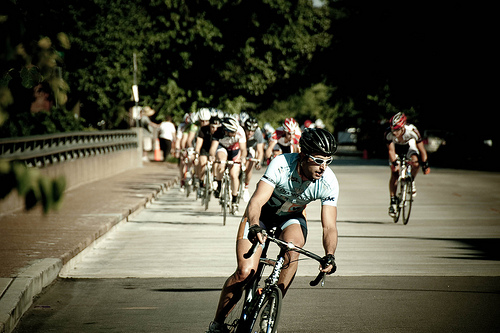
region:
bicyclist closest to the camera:
[207, 126, 341, 330]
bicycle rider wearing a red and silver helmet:
[381, 113, 429, 228]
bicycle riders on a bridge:
[172, 102, 431, 332]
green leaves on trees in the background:
[0, 2, 299, 84]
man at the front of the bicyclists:
[216, 127, 340, 328]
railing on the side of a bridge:
[0, 127, 143, 161]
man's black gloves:
[246, 222, 335, 274]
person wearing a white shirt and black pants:
[157, 115, 175, 161]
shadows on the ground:
[417, 228, 499, 268]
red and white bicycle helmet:
[281, 118, 298, 133]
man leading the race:
[216, 128, 368, 332]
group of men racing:
[172, 96, 429, 332]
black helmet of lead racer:
[296, 124, 335, 155]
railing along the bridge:
[2, 106, 144, 205]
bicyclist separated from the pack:
[385, 111, 420, 226]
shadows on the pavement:
[151, 194, 498, 298]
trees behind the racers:
[8, 4, 499, 141]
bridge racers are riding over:
[94, 139, 495, 332]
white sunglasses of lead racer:
[305, 151, 333, 166]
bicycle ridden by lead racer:
[200, 227, 337, 332]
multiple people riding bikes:
[103, 48, 474, 330]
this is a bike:
[225, 205, 343, 330]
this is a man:
[198, 121, 374, 329]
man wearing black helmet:
[288, 102, 351, 187]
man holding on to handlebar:
[245, 218, 344, 298]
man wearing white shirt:
[256, 147, 344, 234]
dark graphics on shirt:
[262, 153, 334, 230]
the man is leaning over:
[194, 122, 359, 321]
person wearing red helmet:
[386, 112, 408, 135]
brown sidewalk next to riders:
[18, 119, 197, 330]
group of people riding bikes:
[103, 77, 454, 330]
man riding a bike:
[170, 121, 359, 330]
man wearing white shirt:
[255, 147, 345, 227]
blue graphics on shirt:
[263, 154, 336, 218]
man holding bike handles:
[242, 211, 354, 289]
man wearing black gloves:
[237, 222, 347, 287]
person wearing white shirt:
[154, 118, 180, 142]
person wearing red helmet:
[376, 111, 416, 132]